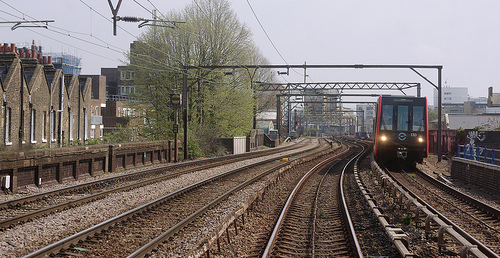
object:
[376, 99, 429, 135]
windshield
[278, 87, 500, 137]
city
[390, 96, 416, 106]
window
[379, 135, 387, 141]
headlights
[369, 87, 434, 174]
chain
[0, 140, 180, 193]
fence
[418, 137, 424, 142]
headlights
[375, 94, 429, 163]
front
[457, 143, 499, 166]
fence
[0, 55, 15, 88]
roofs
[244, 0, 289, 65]
wires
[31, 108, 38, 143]
framed window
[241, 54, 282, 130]
trees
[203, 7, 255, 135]
trees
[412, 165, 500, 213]
track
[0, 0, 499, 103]
sky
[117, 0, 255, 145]
green trees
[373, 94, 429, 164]
train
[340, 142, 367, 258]
track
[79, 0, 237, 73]
power lines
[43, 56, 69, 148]
building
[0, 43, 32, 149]
building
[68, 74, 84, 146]
building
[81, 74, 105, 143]
building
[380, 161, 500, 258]
track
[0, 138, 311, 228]
track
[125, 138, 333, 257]
track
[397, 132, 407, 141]
logo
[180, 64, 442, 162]
caboose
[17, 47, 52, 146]
building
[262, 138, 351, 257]
track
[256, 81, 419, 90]
structure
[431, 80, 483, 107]
white building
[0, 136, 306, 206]
track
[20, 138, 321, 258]
track